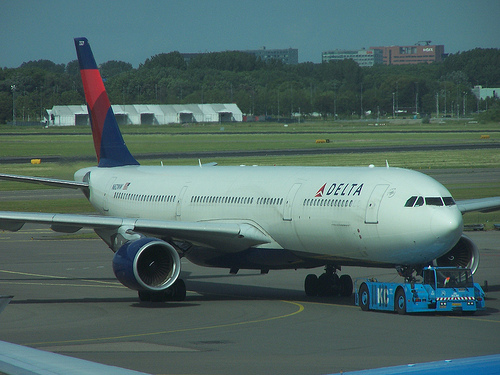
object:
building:
[372, 45, 442, 72]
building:
[320, 49, 384, 67]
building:
[44, 102, 245, 128]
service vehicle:
[354, 265, 485, 315]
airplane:
[1, 35, 500, 304]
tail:
[73, 35, 139, 167]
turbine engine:
[113, 237, 181, 290]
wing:
[0, 210, 270, 249]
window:
[424, 193, 443, 207]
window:
[441, 196, 456, 206]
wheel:
[304, 272, 320, 296]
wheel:
[338, 273, 353, 298]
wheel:
[173, 279, 188, 302]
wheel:
[321, 273, 333, 298]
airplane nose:
[436, 211, 462, 238]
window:
[349, 200, 353, 207]